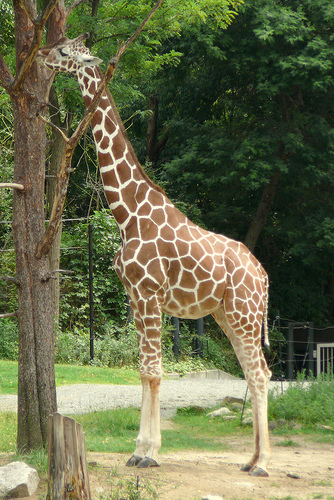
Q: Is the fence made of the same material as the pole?
A: Yes, both the fence and the pole are made of metal.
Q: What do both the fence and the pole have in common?
A: The material, both the fence and the pole are metallic.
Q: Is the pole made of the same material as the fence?
A: Yes, both the pole and the fence are made of metal.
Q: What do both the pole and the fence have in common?
A: The material, both the pole and the fence are metallic.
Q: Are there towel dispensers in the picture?
A: No, there are no towel dispensers.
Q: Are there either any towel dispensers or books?
A: No, there are no towel dispensers or books.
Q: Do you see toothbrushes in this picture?
A: No, there are no toothbrushes.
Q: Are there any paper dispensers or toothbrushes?
A: No, there are no toothbrushes or paper dispensers.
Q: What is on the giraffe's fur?
A: The spots are on the fur.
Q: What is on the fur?
A: The spots are on the fur.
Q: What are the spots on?
A: The spots are on the fur.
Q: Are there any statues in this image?
A: No, there are no statues.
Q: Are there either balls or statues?
A: No, there are no statues or balls.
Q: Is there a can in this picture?
A: No, there are no cans.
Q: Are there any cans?
A: No, there are no cans.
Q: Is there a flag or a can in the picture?
A: No, there are no cans or flags.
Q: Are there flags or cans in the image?
A: No, there are no cans or flags.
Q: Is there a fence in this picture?
A: Yes, there is a fence.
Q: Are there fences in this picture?
A: Yes, there is a fence.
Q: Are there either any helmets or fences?
A: Yes, there is a fence.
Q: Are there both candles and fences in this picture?
A: No, there is a fence but no candles.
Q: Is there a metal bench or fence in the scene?
A: Yes, there is a metal fence.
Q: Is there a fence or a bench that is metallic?
A: Yes, the fence is metallic.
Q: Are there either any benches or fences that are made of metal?
A: Yes, the fence is made of metal.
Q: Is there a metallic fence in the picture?
A: Yes, there is a metal fence.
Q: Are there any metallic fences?
A: Yes, there is a metal fence.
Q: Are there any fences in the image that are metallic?
A: Yes, there is a fence that is metallic.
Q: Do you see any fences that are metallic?
A: Yes, there is a fence that is metallic.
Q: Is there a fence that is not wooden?
A: Yes, there is a metallic fence.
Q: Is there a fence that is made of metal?
A: Yes, there is a fence that is made of metal.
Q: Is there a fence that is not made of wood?
A: Yes, there is a fence that is made of metal.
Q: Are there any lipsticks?
A: No, there are no lipsticks.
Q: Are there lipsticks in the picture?
A: No, there are no lipsticks.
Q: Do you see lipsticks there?
A: No, there are no lipsticks.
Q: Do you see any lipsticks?
A: No, there are no lipsticks.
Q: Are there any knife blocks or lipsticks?
A: No, there are no lipsticks or knife blocks.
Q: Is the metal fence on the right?
A: Yes, the fence is on the right of the image.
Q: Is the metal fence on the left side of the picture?
A: No, the fence is on the right of the image.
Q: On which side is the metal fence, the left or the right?
A: The fence is on the right of the image.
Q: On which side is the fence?
A: The fence is on the right of the image.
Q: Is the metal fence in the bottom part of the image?
A: Yes, the fence is in the bottom of the image.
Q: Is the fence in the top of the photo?
A: No, the fence is in the bottom of the image.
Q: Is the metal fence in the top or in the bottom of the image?
A: The fence is in the bottom of the image.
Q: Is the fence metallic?
A: Yes, the fence is metallic.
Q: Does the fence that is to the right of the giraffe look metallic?
A: Yes, the fence is metallic.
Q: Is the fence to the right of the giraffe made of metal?
A: Yes, the fence is made of metal.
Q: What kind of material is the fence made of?
A: The fence is made of metal.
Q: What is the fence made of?
A: The fence is made of metal.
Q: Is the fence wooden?
A: No, the fence is metallic.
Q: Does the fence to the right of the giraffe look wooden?
A: No, the fence is metallic.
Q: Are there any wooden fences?
A: No, there is a fence but it is metallic.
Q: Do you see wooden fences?
A: No, there is a fence but it is metallic.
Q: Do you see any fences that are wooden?
A: No, there is a fence but it is metallic.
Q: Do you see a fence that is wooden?
A: No, there is a fence but it is metallic.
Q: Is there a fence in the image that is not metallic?
A: No, there is a fence but it is metallic.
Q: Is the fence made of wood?
A: No, the fence is made of metal.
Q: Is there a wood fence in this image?
A: No, there is a fence but it is made of metal.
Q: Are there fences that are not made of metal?
A: No, there is a fence but it is made of metal.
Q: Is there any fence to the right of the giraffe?
A: Yes, there is a fence to the right of the giraffe.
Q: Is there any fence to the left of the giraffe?
A: No, the fence is to the right of the giraffe.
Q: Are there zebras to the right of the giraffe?
A: No, there is a fence to the right of the giraffe.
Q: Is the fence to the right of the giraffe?
A: Yes, the fence is to the right of the giraffe.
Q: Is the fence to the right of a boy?
A: No, the fence is to the right of the giraffe.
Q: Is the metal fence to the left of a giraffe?
A: No, the fence is to the right of a giraffe.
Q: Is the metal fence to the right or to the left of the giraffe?
A: The fence is to the right of the giraffe.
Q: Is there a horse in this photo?
A: No, there are no horses.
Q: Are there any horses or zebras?
A: No, there are no horses or zebras.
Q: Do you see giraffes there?
A: Yes, there is a giraffe.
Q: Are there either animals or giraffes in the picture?
A: Yes, there is a giraffe.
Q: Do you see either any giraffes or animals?
A: Yes, there is a giraffe.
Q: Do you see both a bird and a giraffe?
A: No, there is a giraffe but no birds.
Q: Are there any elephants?
A: No, there are no elephants.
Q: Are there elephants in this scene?
A: No, there are no elephants.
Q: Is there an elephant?
A: No, there are no elephants.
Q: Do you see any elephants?
A: No, there are no elephants.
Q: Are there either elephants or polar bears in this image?
A: No, there are no elephants or polar bears.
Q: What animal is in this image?
A: The animal is a giraffe.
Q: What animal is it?
A: The animal is a giraffe.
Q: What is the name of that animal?
A: This is a giraffe.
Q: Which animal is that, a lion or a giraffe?
A: This is a giraffe.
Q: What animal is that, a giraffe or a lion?
A: This is a giraffe.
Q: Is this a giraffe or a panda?
A: This is a giraffe.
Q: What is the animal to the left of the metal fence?
A: The animal is a giraffe.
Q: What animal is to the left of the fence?
A: The animal is a giraffe.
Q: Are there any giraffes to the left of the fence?
A: Yes, there is a giraffe to the left of the fence.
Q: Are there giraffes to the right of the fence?
A: No, the giraffe is to the left of the fence.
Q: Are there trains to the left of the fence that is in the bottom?
A: No, there is a giraffe to the left of the fence.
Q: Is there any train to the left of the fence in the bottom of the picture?
A: No, there is a giraffe to the left of the fence.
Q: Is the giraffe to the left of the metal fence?
A: Yes, the giraffe is to the left of the fence.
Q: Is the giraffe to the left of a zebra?
A: No, the giraffe is to the left of the fence.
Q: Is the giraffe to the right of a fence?
A: No, the giraffe is to the left of a fence.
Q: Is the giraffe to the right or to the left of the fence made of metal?
A: The giraffe is to the left of the fence.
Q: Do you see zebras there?
A: No, there are no zebras.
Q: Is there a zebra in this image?
A: No, there are no zebras.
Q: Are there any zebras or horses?
A: No, there are no zebras or horses.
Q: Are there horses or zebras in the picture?
A: No, there are no zebras or horses.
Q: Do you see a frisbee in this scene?
A: No, there are no frisbees.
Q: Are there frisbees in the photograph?
A: No, there are no frisbees.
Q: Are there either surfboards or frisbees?
A: No, there are no frisbees or surfboards.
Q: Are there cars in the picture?
A: No, there are no cars.